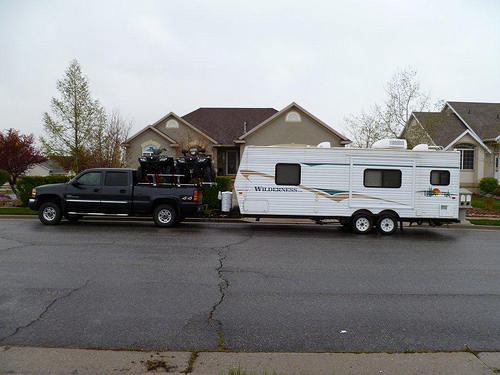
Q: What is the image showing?
A: It is showing a road.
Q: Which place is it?
A: It is a road.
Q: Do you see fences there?
A: No, there are no fences.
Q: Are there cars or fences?
A: No, there are no fences or cars.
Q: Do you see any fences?
A: No, there are no fences.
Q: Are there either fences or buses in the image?
A: No, there are no fences or buses.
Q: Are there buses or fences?
A: No, there are no fences or buses.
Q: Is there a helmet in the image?
A: No, there are no helmets.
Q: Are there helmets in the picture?
A: No, there are no helmets.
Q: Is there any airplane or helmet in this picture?
A: No, there are no helmets or airplanes.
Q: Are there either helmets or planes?
A: No, there are no helmets or planes.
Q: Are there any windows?
A: Yes, there is a window.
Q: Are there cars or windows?
A: Yes, there is a window.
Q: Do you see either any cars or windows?
A: Yes, there is a window.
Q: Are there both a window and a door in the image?
A: Yes, there are both a window and a door.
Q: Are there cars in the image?
A: No, there are no cars.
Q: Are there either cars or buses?
A: No, there are no cars or buses.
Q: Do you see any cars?
A: No, there are no cars.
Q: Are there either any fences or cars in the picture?
A: No, there are no cars or fences.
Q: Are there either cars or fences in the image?
A: No, there are no cars or fences.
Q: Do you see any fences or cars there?
A: No, there are no cars or fences.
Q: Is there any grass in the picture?
A: Yes, there is grass.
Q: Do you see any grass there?
A: Yes, there is grass.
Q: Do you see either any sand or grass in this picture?
A: Yes, there is grass.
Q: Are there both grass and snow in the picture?
A: No, there is grass but no snow.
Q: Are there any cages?
A: No, there are no cages.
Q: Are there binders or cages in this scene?
A: No, there are no cages or binders.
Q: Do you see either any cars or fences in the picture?
A: No, there are no fences or cars.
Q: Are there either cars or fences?
A: No, there are no fences or cars.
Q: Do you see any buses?
A: No, there are no buses.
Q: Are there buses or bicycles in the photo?
A: No, there are no buses or bicycles.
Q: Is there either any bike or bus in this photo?
A: No, there are no buses or bikes.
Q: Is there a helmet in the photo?
A: No, there are no helmets.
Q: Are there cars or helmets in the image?
A: No, there are no helmets or cars.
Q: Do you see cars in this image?
A: No, there are no cars.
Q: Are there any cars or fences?
A: No, there are no cars or fences.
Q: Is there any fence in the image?
A: No, there are no fences.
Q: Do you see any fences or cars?
A: No, there are no fences or cars.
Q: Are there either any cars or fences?
A: No, there are no fences or cars.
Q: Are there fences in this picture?
A: No, there are no fences.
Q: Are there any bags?
A: No, there are no bags.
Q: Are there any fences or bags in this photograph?
A: No, there are no bags or fences.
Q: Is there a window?
A: Yes, there is a window.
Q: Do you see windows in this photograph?
A: Yes, there is a window.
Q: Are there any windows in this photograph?
A: Yes, there is a window.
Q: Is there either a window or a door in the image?
A: Yes, there is a window.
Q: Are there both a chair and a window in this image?
A: No, there is a window but no chairs.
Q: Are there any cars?
A: No, there are no cars.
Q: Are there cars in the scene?
A: No, there are no cars.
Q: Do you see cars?
A: No, there are no cars.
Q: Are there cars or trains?
A: No, there are no cars or trains.